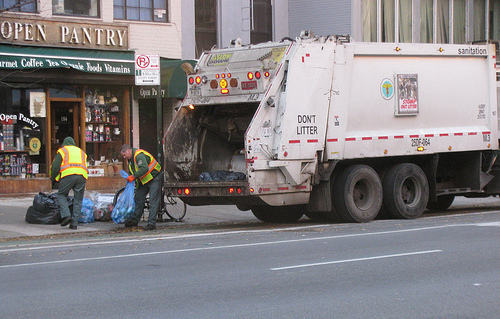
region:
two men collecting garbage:
[22, 129, 187, 228]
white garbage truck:
[168, 24, 496, 202]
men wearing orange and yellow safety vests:
[53, 145, 162, 190]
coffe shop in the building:
[0, 15, 140, 193]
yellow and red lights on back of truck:
[180, 62, 285, 102]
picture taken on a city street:
[22, 23, 463, 278]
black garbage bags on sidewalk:
[22, 188, 77, 226]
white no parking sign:
[129, 48, 170, 90]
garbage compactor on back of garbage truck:
[162, 45, 284, 200]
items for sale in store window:
[88, 89, 130, 156]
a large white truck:
[158, 40, 496, 228]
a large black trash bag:
[27, 189, 62, 225]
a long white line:
[265, 240, 443, 282]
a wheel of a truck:
[338, 165, 390, 218]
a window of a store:
[85, 85, 125, 163]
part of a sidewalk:
[0, 193, 34, 238]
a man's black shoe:
[58, 213, 73, 228]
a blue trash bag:
[105, 167, 137, 223]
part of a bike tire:
[158, 193, 188, 219]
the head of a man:
[119, 145, 135, 162]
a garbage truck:
[190, 37, 492, 202]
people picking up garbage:
[41, 135, 163, 224]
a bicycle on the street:
[163, 195, 189, 217]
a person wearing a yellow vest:
[50, 138, 93, 225]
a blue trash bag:
[111, 173, 136, 220]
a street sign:
[131, 55, 166, 92]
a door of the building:
[46, 101, 81, 148]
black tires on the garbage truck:
[340, 166, 426, 211]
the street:
[10, 243, 497, 316]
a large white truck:
[175, 43, 497, 189]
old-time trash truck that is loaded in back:
[158, 31, 497, 225]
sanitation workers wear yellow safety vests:
[50, 140, 91, 183]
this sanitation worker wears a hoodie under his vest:
[45, 133, 90, 183]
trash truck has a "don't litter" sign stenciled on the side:
[286, 106, 321, 137]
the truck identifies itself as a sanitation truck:
[452, 40, 487, 57]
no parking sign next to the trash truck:
[132, 50, 158, 86]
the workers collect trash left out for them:
[20, 132, 170, 232]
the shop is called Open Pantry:
[0, 5, 136, 195]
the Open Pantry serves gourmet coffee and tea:
[0, 50, 61, 75]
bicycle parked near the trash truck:
[108, 182, 186, 222]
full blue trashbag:
[113, 171, 135, 226]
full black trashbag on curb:
[26, 190, 56, 222]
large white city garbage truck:
[161, 30, 498, 222]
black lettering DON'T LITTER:
[295, 113, 318, 135]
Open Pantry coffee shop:
[0, 12, 138, 196]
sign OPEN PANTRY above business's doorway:
[0, 11, 130, 48]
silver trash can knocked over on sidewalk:
[94, 192, 115, 221]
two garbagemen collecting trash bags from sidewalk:
[26, 135, 164, 231]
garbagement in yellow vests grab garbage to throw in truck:
[26, 28, 498, 233]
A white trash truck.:
[161, 34, 498, 220]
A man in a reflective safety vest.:
[48, 136, 89, 234]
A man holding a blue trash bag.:
[114, 143, 166, 232]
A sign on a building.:
[0, 13, 132, 45]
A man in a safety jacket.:
[118, 143, 167, 233]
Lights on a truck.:
[228, 182, 245, 196]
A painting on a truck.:
[392, 69, 420, 119]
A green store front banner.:
[0, 42, 141, 79]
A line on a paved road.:
[269, 243, 444, 271]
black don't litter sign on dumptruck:
[295, 112, 318, 136]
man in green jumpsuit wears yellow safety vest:
[50, 134, 85, 229]